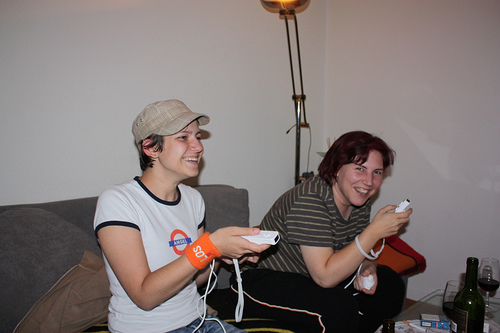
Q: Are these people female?
A: Yes, all the people are female.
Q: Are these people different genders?
A: No, all the people are female.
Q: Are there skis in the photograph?
A: No, there are no skis.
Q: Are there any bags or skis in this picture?
A: No, there are no skis or bags.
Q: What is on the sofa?
A: The jacket is on the sofa.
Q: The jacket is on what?
A: The jacket is on the sofa.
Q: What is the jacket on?
A: The jacket is on the sofa.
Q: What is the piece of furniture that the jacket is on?
A: The piece of furniture is a sofa.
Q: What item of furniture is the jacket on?
A: The jacket is on the sofa.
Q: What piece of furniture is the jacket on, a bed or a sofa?
A: The jacket is on a sofa.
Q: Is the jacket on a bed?
A: No, the jacket is on the sofa.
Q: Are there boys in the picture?
A: No, there are no boys.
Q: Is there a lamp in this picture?
A: Yes, there is a lamp.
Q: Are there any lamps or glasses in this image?
A: Yes, there is a lamp.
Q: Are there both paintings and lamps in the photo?
A: No, there is a lamp but no paintings.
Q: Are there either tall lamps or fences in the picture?
A: Yes, there is a tall lamp.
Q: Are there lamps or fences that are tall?
A: Yes, the lamp is tall.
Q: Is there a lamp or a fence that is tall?
A: Yes, the lamp is tall.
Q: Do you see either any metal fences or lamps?
A: Yes, there is a metal lamp.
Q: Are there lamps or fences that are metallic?
A: Yes, the lamp is metallic.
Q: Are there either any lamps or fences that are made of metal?
A: Yes, the lamp is made of metal.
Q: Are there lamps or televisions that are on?
A: Yes, the lamp is on.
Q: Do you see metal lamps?
A: Yes, there is a metal lamp.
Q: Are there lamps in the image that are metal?
A: Yes, there is a metal lamp.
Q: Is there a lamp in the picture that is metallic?
A: Yes, there is a lamp that is metallic.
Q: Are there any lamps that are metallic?
A: Yes, there is a lamp that is metallic.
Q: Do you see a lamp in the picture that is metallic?
A: Yes, there is a lamp that is metallic.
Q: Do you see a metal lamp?
A: Yes, there is a lamp that is made of metal.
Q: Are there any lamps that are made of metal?
A: Yes, there is a lamp that is made of metal.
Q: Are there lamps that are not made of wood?
A: Yes, there is a lamp that is made of metal.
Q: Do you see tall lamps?
A: Yes, there is a tall lamp.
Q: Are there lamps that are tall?
A: Yes, there is a lamp that is tall.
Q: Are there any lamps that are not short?
A: Yes, there is a tall lamp.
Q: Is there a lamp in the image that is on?
A: Yes, there is a lamp that is on.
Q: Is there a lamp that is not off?
A: Yes, there is a lamp that is on.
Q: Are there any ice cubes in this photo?
A: No, there are no ice cubes.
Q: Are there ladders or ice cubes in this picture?
A: No, there are no ice cubes or ladders.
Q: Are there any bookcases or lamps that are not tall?
A: No, there is a lamp but it is tall.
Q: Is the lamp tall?
A: Yes, the lamp is tall.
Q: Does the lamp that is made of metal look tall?
A: Yes, the lamp is tall.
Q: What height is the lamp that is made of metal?
A: The lamp is tall.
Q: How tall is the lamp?
A: The lamp is tall.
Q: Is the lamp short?
A: No, the lamp is tall.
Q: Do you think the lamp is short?
A: No, the lamp is tall.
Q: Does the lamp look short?
A: No, the lamp is tall.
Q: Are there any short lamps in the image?
A: No, there is a lamp but it is tall.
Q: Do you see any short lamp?
A: No, there is a lamp but it is tall.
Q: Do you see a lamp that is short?
A: No, there is a lamp but it is tall.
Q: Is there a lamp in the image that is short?
A: No, there is a lamp but it is tall.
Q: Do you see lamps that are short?
A: No, there is a lamp but it is tall.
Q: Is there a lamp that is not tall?
A: No, there is a lamp but it is tall.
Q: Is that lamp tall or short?
A: The lamp is tall.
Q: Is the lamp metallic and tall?
A: Yes, the lamp is metallic and tall.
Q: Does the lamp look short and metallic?
A: No, the lamp is metallic but tall.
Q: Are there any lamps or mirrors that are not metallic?
A: No, there is a lamp but it is metallic.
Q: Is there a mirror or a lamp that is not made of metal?
A: No, there is a lamp but it is made of metal.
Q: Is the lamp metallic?
A: Yes, the lamp is metallic.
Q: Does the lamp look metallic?
A: Yes, the lamp is metallic.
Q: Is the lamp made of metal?
A: Yes, the lamp is made of metal.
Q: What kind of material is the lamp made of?
A: The lamp is made of metal.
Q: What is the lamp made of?
A: The lamp is made of metal.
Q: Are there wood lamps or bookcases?
A: No, there is a lamp but it is metallic.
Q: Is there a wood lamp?
A: No, there is a lamp but it is made of metal.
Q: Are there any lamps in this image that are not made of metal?
A: No, there is a lamp but it is made of metal.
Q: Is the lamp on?
A: Yes, the lamp is on.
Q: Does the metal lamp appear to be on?
A: Yes, the lamp is on.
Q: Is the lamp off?
A: No, the lamp is on.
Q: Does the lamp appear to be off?
A: No, the lamp is on.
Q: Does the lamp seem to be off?
A: No, the lamp is on.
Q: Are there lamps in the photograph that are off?
A: No, there is a lamp but it is on.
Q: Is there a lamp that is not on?
A: No, there is a lamp but it is on.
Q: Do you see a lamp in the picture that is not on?
A: No, there is a lamp but it is on.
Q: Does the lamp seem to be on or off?
A: The lamp is on.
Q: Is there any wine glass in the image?
A: Yes, there is a wine glass.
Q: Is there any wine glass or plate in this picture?
A: Yes, there is a wine glass.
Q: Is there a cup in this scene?
A: No, there are no cups.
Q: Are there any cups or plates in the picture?
A: No, there are no cups or plates.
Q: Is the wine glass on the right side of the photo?
A: Yes, the wine glass is on the right of the image.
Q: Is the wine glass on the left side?
A: No, the wine glass is on the right of the image.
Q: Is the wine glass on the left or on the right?
A: The wine glass is on the right of the image.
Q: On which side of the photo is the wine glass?
A: The wine glass is on the right of the image.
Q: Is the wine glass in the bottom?
A: Yes, the wine glass is in the bottom of the image.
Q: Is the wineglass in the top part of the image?
A: No, the wineglass is in the bottom of the image.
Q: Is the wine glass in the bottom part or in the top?
A: The wine glass is in the bottom of the image.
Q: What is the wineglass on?
A: The wineglass is on the coffee table.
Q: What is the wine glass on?
A: The wineglass is on the coffee table.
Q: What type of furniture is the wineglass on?
A: The wineglass is on the coffee table.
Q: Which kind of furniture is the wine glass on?
A: The wineglass is on the coffee table.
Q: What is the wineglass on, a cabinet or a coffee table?
A: The wineglass is on a coffee table.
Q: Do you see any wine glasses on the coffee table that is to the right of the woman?
A: Yes, there is a wine glass on the coffee table.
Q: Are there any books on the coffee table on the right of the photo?
A: No, there is a wine glass on the coffee table.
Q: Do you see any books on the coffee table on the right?
A: No, there is a wine glass on the coffee table.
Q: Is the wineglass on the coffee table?
A: Yes, the wineglass is on the coffee table.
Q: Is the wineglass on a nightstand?
A: No, the wineglass is on the coffee table.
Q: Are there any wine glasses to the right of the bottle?
A: Yes, there is a wine glass to the right of the bottle.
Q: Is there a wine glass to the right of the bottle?
A: Yes, there is a wine glass to the right of the bottle.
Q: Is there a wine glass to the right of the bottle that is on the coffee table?
A: Yes, there is a wine glass to the right of the bottle.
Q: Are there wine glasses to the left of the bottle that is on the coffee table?
A: No, the wine glass is to the right of the bottle.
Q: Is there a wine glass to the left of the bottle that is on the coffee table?
A: No, the wine glass is to the right of the bottle.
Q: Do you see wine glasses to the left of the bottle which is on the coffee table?
A: No, the wine glass is to the right of the bottle.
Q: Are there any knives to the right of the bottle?
A: No, there is a wine glass to the right of the bottle.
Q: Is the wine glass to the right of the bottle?
A: Yes, the wine glass is to the right of the bottle.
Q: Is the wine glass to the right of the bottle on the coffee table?
A: Yes, the wine glass is to the right of the bottle.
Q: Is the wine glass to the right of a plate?
A: No, the wine glass is to the right of the bottle.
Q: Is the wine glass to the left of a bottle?
A: No, the wine glass is to the right of a bottle.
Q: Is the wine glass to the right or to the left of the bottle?
A: The wine glass is to the right of the bottle.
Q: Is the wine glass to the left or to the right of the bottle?
A: The wine glass is to the right of the bottle.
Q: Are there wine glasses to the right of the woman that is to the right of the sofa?
A: Yes, there is a wine glass to the right of the woman.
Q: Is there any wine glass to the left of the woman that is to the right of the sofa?
A: No, the wine glass is to the right of the woman.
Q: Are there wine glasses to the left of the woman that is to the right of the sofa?
A: No, the wine glass is to the right of the woman.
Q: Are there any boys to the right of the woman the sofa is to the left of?
A: No, there is a wine glass to the right of the woman.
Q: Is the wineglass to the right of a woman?
A: Yes, the wineglass is to the right of a woman.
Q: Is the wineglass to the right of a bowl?
A: No, the wineglass is to the right of a woman.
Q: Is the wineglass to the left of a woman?
A: No, the wineglass is to the right of a woman.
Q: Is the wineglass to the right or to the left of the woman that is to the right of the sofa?
A: The wineglass is to the right of the woman.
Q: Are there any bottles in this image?
A: Yes, there is a bottle.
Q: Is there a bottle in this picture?
A: Yes, there is a bottle.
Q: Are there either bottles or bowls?
A: Yes, there is a bottle.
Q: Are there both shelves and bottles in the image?
A: No, there is a bottle but no shelves.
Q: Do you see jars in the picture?
A: No, there are no jars.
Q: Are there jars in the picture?
A: No, there are no jars.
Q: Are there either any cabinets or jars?
A: No, there are no jars or cabinets.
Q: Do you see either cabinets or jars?
A: No, there are no jars or cabinets.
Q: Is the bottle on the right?
A: Yes, the bottle is on the right of the image.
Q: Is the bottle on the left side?
A: No, the bottle is on the right of the image.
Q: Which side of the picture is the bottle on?
A: The bottle is on the right of the image.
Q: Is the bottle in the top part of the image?
A: No, the bottle is in the bottom of the image.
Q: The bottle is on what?
A: The bottle is on the coffee table.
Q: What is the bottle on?
A: The bottle is on the coffee table.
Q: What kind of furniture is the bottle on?
A: The bottle is on the coffee table.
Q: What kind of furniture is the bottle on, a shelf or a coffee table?
A: The bottle is on a coffee table.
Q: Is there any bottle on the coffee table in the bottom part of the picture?
A: Yes, there is a bottle on the coffee table.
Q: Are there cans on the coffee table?
A: No, there is a bottle on the coffee table.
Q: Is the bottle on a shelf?
A: No, the bottle is on a coffee table.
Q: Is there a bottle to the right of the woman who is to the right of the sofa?
A: Yes, there is a bottle to the right of the woman.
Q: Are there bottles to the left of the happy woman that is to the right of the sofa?
A: No, the bottle is to the right of the woman.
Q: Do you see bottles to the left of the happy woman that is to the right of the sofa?
A: No, the bottle is to the right of the woman.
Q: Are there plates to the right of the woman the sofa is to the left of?
A: No, there is a bottle to the right of the woman.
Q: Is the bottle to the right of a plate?
A: No, the bottle is to the right of the woman.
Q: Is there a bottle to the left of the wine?
A: Yes, there is a bottle to the left of the wine.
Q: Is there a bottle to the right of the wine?
A: No, the bottle is to the left of the wine.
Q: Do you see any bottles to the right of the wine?
A: No, the bottle is to the left of the wine.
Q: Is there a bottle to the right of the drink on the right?
A: No, the bottle is to the left of the wine.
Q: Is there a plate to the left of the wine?
A: No, there is a bottle to the left of the wine.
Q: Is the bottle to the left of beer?
A: No, the bottle is to the left of the wine.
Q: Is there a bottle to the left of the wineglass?
A: Yes, there is a bottle to the left of the wineglass.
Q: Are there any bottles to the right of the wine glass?
A: No, the bottle is to the left of the wine glass.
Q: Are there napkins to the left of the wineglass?
A: No, there is a bottle to the left of the wineglass.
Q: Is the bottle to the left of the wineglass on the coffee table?
A: Yes, the bottle is to the left of the wine glass.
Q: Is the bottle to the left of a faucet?
A: No, the bottle is to the left of the wine glass.